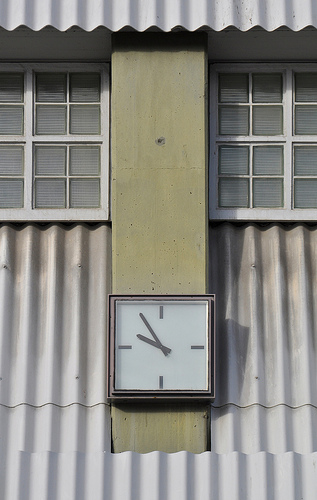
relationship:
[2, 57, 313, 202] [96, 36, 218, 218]
windows on either side of pillar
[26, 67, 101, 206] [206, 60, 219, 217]
window with frame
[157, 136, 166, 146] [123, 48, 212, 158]
hole in cement beam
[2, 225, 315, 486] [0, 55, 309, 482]
tin covers wall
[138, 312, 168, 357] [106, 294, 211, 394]
hand on clock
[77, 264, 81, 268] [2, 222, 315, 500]
screws holding tin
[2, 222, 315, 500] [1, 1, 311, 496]
tin on wall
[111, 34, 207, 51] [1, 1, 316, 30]
shadow of roof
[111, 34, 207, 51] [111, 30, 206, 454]
shadow on cement pillar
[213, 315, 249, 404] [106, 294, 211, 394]
shadow of clock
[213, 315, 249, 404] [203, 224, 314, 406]
shadow on tin siding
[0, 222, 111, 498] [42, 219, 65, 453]
tin siding has ridges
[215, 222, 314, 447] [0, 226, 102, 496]
panels are on wall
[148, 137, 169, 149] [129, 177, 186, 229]
hole in wall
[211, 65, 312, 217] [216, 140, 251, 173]
window has glass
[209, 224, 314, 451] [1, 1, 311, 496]
aluminum plates lines wall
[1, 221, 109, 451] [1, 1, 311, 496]
aluminum plates lines wall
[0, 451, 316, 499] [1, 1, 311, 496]
aluminum plates lines wall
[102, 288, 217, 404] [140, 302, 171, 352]
clock has big hand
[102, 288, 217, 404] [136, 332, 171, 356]
clock has hand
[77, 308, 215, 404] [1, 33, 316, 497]
clock of a building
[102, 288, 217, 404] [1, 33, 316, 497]
clock of a building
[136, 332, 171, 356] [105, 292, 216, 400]
hand of a clock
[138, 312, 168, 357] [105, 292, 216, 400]
hand of a clock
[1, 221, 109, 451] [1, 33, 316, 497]
aluminum plates of a building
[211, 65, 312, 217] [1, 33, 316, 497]
window of building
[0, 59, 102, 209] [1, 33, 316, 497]
window of building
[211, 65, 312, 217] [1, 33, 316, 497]
window of a building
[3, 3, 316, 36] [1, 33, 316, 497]
siding of a building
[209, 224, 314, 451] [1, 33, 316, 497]
aluminum plates of a building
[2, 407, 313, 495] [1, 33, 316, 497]
siding of a building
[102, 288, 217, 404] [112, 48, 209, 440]
clock on pillar